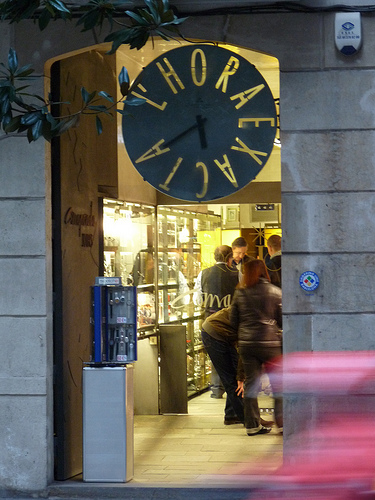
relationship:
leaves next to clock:
[0, 55, 141, 139] [120, 42, 276, 201]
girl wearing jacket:
[225, 255, 282, 436] [222, 279, 284, 350]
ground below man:
[133, 412, 296, 481] [192, 244, 242, 399]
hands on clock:
[195, 109, 208, 150] [120, 42, 276, 201]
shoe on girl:
[240, 415, 274, 451] [225, 255, 282, 436]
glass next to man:
[103, 200, 204, 285] [192, 244, 242, 399]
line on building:
[281, 63, 374, 76] [76, 23, 371, 497]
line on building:
[281, 124, 373, 136] [76, 23, 371, 497]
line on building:
[279, 187, 371, 197] [76, 23, 371, 497]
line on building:
[281, 249, 373, 256] [76, 23, 371, 497]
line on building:
[283, 307, 373, 315] [76, 23, 371, 497]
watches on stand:
[98, 281, 142, 366] [73, 353, 139, 486]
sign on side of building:
[294, 266, 322, 298] [4, 2, 374, 489]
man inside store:
[192, 244, 242, 399] [3, 30, 373, 490]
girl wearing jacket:
[225, 255, 282, 436] [227, 277, 284, 346]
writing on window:
[170, 293, 228, 318] [47, 52, 268, 481]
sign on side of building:
[60, 198, 97, 250] [4, 2, 374, 489]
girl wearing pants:
[225, 255, 282, 436] [236, 341, 282, 431]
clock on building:
[120, 42, 276, 201] [4, 2, 374, 489]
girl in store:
[225, 255, 282, 436] [3, 30, 373, 490]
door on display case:
[158, 323, 188, 417] [100, 195, 157, 335]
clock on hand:
[117, 41, 281, 204] [161, 120, 195, 152]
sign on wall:
[298, 266, 322, 296] [279, 4, 372, 485]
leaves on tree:
[0, 47, 156, 146] [0, 1, 221, 155]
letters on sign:
[132, 84, 168, 111] [114, 44, 272, 209]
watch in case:
[107, 295, 118, 304] [92, 278, 136, 369]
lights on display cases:
[100, 196, 158, 245] [102, 198, 220, 396]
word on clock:
[127, 45, 273, 202] [120, 42, 276, 201]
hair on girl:
[243, 275, 267, 309] [225, 255, 282, 436]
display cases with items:
[102, 198, 220, 396] [127, 223, 210, 325]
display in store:
[88, 191, 226, 393] [54, 1, 287, 468]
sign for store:
[55, 197, 108, 260] [58, 64, 274, 470]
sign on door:
[55, 197, 108, 260] [56, 82, 110, 478]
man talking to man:
[192, 244, 242, 399] [231, 236, 255, 283]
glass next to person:
[156, 211, 221, 382] [263, 234, 283, 278]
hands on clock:
[159, 111, 216, 156] [121, 25, 275, 211]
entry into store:
[35, 29, 287, 493] [52, 51, 284, 468]